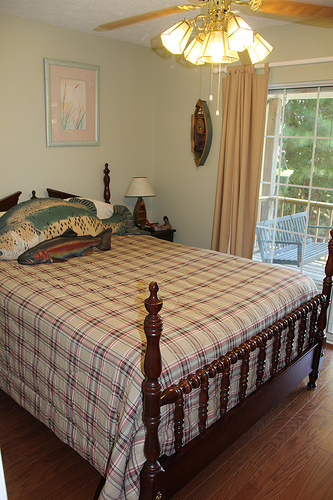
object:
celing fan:
[92, 1, 332, 32]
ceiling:
[1, 0, 332, 51]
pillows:
[0, 196, 137, 263]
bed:
[2, 162, 332, 499]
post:
[141, 279, 167, 498]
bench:
[254, 211, 332, 265]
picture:
[44, 58, 98, 147]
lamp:
[122, 176, 157, 228]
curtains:
[209, 62, 271, 260]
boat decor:
[189, 100, 213, 168]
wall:
[2, 22, 226, 249]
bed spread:
[0, 227, 321, 498]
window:
[252, 83, 331, 264]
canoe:
[133, 198, 147, 229]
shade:
[123, 177, 158, 199]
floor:
[0, 342, 332, 500]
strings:
[215, 63, 223, 120]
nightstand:
[133, 223, 177, 245]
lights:
[160, 8, 276, 118]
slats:
[160, 338, 323, 496]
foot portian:
[123, 223, 333, 498]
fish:
[16, 226, 114, 264]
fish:
[196, 117, 204, 135]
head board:
[0, 164, 112, 217]